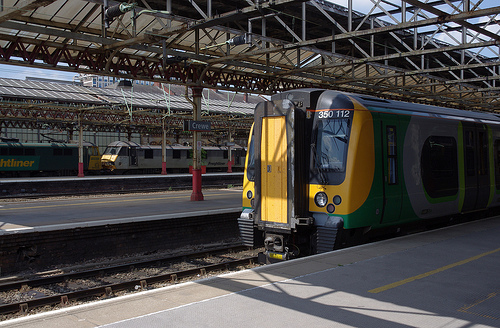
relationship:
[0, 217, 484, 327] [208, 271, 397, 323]
caution area on platform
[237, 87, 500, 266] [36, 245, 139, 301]
train on tracks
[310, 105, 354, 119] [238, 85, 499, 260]
identification number on train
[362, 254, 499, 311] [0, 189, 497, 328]
lines on paved walkway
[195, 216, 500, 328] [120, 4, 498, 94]
shadow from girder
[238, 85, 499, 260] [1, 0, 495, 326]
train in station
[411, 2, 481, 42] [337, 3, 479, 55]
sky seen through girders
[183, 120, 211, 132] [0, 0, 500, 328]
blue sign of station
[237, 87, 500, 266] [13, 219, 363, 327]
train on track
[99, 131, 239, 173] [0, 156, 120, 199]
train on track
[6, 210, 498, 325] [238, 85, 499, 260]
paved walkway next to train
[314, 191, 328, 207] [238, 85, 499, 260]
headlight in front of a train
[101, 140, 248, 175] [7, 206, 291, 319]
train on track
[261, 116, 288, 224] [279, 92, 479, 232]
door on train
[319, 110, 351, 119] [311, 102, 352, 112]
identification number under a line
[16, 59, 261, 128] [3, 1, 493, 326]
roof of train station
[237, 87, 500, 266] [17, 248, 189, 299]
train on track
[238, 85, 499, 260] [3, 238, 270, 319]
train on track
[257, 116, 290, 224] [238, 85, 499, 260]
door of train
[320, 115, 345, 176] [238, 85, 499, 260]
window of train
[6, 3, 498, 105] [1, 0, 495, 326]
roof of station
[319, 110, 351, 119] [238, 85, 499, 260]
identification number of train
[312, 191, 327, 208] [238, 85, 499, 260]
headlight of train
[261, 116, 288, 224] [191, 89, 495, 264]
door of train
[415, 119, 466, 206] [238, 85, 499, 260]
window of train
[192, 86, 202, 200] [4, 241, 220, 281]
metal pole near tracks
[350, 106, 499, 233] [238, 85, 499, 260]
green side of train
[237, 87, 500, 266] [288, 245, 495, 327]
train on platform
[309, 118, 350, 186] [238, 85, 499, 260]
window of train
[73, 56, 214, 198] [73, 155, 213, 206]
steel poles with red bottoms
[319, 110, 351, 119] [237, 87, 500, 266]
identification number on train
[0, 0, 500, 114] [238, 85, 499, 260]
girder above train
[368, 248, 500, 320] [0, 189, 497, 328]
lines on paved walkway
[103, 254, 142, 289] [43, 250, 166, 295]
gravel between tracks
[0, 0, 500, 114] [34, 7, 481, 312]
girder on station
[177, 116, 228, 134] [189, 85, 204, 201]
blue sign on metal pole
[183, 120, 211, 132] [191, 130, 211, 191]
blue sign fastened to pole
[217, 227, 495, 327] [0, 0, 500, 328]
shadow on station